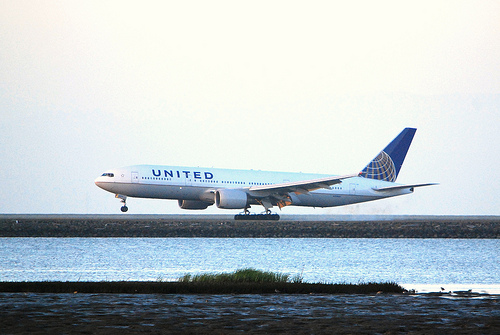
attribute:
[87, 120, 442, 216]
plane — commercial, flying, blue, white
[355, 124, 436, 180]
tail — bright blue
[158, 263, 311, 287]
sea grass — tall, green, growing, low, brown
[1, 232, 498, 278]
water — blue, rippling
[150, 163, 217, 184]
letters — blue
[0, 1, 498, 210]
sky — overcast, white, clear, bright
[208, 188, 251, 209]
wing engine — large, white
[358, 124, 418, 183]
tail — blue, yellow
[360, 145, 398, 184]
logo — yellow, world, sphere, vector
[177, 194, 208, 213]
engine — white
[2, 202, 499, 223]
runway — flat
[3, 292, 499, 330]
space — muddy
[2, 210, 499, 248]
landscape — flat, rocky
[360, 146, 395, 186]
lines — orange, white, blue